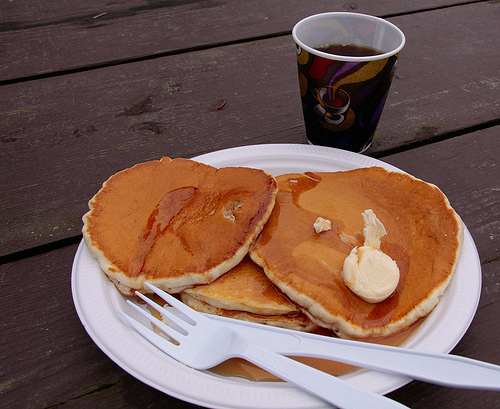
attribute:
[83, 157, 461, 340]
pancakes — brown, flat, round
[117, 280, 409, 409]
fork — plastic, white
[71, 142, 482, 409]
plate — round, white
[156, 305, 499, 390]
knife — white, plastic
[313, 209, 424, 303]
butter — round, yellow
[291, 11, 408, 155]
cup — small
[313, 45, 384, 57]
coffee — black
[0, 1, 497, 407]
table — chipped, wood